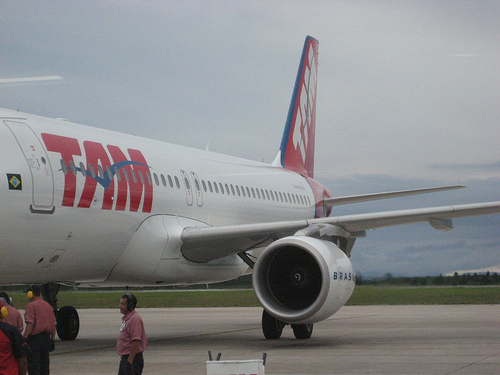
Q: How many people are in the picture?
A: Four.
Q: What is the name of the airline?
A: TAM.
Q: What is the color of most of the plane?
A: White.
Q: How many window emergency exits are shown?
A: Two.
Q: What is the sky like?
A: Cloudy.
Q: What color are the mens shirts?
A: Red.